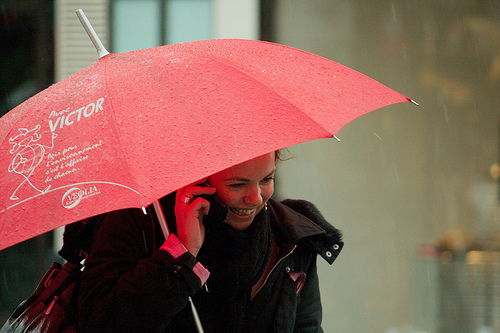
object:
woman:
[84, 148, 328, 331]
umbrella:
[3, 7, 418, 330]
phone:
[200, 179, 229, 224]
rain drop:
[200, 84, 210, 91]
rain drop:
[184, 62, 191, 69]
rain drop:
[196, 63, 203, 69]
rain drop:
[245, 54, 252, 62]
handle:
[150, 199, 205, 332]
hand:
[171, 177, 220, 258]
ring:
[180, 195, 191, 206]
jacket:
[81, 194, 334, 332]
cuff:
[158, 233, 210, 287]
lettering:
[43, 97, 124, 185]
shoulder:
[76, 202, 162, 268]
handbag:
[0, 214, 95, 333]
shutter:
[51, 0, 110, 79]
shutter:
[210, 3, 267, 44]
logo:
[6, 124, 59, 201]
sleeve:
[78, 212, 211, 330]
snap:
[325, 250, 333, 258]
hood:
[272, 197, 344, 266]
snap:
[331, 242, 341, 250]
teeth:
[230, 207, 255, 216]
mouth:
[228, 203, 263, 218]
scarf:
[207, 210, 275, 332]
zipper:
[246, 238, 304, 295]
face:
[209, 152, 276, 230]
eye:
[228, 181, 246, 191]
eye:
[260, 174, 273, 186]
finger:
[180, 184, 217, 203]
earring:
[264, 199, 269, 212]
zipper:
[45, 293, 60, 317]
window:
[110, 3, 217, 55]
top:
[75, 7, 110, 62]